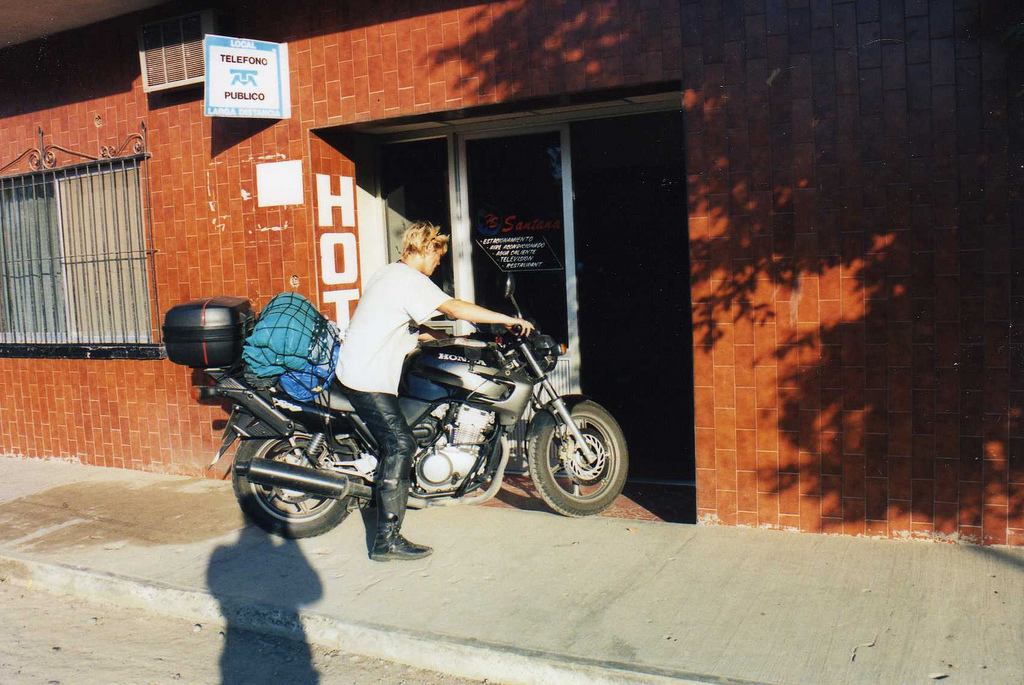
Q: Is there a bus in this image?
A: No, there are no buses.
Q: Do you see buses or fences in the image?
A: No, there are no buses or fences.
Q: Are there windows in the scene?
A: Yes, there is a window.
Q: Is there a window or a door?
A: Yes, there is a window.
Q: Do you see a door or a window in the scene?
A: Yes, there is a window.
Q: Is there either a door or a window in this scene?
A: Yes, there is a window.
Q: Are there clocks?
A: No, there are no clocks.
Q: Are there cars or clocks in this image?
A: No, there are no clocks or cars.